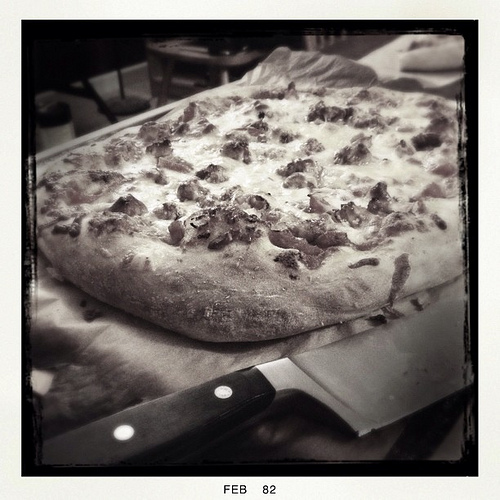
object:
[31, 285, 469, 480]
knife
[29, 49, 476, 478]
board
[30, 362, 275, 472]
handle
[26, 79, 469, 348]
pizza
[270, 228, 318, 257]
sausage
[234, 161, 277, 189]
cheese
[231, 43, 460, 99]
paper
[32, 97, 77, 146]
basket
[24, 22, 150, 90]
wall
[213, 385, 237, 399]
bolt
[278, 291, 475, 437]
blade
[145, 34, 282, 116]
chair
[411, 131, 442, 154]
olive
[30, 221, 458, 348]
crust